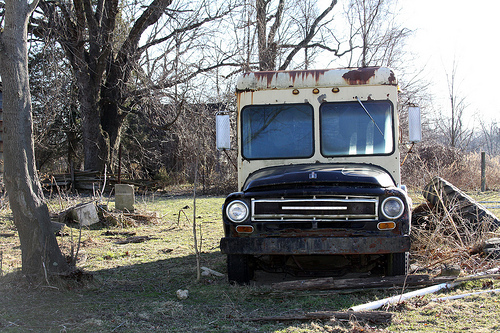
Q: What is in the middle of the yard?
A: Truck.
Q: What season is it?
A: Winter.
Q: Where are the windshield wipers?
A: On top of the windows.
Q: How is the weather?
A: Sunny.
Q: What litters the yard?
A: Abandoned garbage.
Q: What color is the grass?
A: Green.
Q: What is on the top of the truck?
A: Rust spots.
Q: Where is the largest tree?
A: On the left.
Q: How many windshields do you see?
A: Two.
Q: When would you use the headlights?
A: Nightime driving.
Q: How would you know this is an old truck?
A: The rust.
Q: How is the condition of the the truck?
A: Not in good working shape.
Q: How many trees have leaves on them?
A: None.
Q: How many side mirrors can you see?
A: Two.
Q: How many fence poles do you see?
A: One.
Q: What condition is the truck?
A: Old and rusted.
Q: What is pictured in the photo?
A: A rusty, old truck.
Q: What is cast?
A: A shadow.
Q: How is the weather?
A: Sunny.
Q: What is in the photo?
A: A vintage bus.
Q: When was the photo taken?
A: Daytime.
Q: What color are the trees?
A: Brown.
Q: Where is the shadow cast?
A: On the ground.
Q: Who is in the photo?
A: Noone.